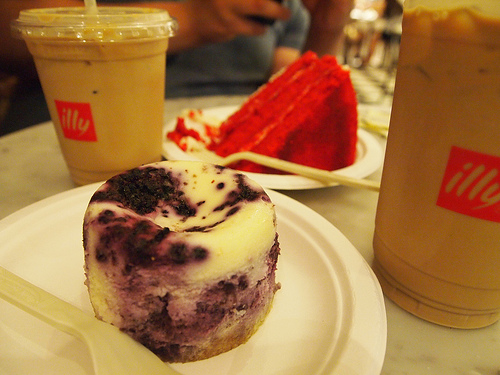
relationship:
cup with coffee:
[7, 0, 176, 180] [370, 2, 499, 332]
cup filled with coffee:
[371, 0, 498, 328] [370, 2, 499, 332]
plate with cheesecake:
[1, 167, 391, 373] [80, 160, 282, 363]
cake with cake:
[82, 158, 278, 363] [212, 51, 362, 170]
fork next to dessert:
[1, 265, 170, 375] [70, 143, 297, 367]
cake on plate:
[212, 57, 362, 167] [158, 103, 381, 188]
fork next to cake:
[162, 138, 380, 192] [214, 48, 359, 183]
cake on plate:
[212, 57, 362, 167] [178, 110, 416, 219]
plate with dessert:
[1, 167, 387, 375] [122, 174, 327, 356]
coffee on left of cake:
[21, 26, 190, 185] [177, 50, 362, 172]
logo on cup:
[49, 92, 101, 144] [7, 0, 176, 180]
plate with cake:
[1, 167, 391, 373] [82, 158, 278, 363]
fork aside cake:
[162, 138, 380, 192] [211, 47, 356, 169]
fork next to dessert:
[1, 265, 170, 375] [76, 135, 317, 368]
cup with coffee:
[7, 0, 176, 180] [21, 26, 190, 185]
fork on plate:
[1, 265, 174, 370] [1, 167, 391, 373]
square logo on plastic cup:
[442, 142, 494, 219] [27, 19, 163, 178]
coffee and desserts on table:
[54, 31, 188, 142] [407, 318, 494, 328]